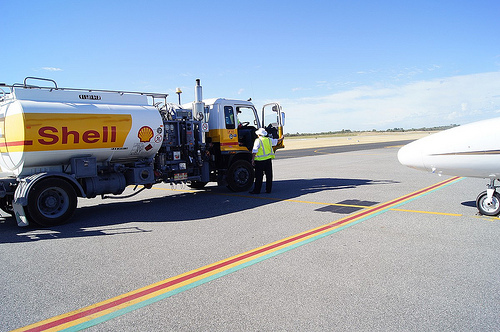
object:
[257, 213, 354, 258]
line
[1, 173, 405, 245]
shadow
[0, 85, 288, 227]
truck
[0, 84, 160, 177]
tank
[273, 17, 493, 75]
sky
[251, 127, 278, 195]
man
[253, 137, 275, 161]
vest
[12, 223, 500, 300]
ground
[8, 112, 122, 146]
sign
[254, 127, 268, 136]
hat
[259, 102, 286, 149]
door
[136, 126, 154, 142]
logo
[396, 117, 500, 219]
plane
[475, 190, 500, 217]
wheel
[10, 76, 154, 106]
top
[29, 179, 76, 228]
tire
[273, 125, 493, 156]
street